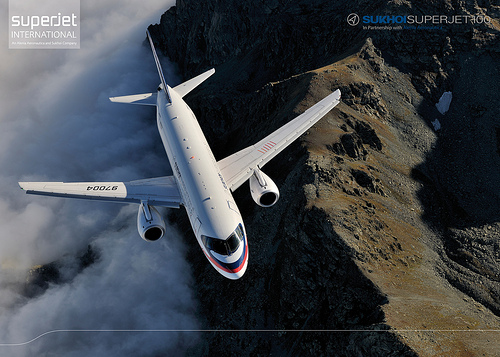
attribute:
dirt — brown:
[336, 194, 429, 318]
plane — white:
[13, 21, 413, 335]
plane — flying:
[20, 34, 342, 279]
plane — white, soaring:
[12, 25, 347, 292]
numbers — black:
[75, 178, 123, 203]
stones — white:
[417, 80, 459, 139]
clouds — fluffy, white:
[3, 255, 160, 325]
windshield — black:
[201, 224, 245, 259]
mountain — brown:
[256, 54, 477, 353]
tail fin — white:
[139, 25, 180, 117]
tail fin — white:
[169, 68, 213, 103]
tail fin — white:
[103, 89, 163, 111]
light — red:
[187, 154, 196, 162]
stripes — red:
[257, 140, 279, 154]